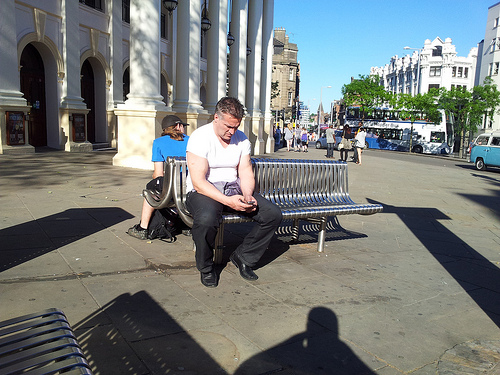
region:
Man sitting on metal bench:
[185, 95, 282, 286]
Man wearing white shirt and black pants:
[183, 98, 277, 286]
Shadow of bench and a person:
[10, 287, 392, 373]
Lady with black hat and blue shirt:
[128, 112, 188, 244]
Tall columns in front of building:
[114, 0, 274, 147]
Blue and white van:
[467, 124, 499, 173]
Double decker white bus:
[342, 97, 454, 157]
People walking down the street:
[280, 116, 367, 162]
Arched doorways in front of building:
[13, 27, 118, 156]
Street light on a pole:
[401, 45, 425, 94]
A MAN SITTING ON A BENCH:
[174, 94, 392, 291]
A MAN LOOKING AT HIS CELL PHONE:
[185, 95, 287, 290]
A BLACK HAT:
[156, 112, 194, 130]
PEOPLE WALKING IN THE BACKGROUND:
[336, 120, 368, 166]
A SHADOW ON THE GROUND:
[226, 303, 383, 372]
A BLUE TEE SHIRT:
[149, 132, 195, 165]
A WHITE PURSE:
[335, 139, 345, 151]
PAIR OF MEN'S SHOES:
[195, 249, 269, 290]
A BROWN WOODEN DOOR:
[17, 39, 52, 154]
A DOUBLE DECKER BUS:
[339, 99, 462, 159]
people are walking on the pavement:
[337, 118, 412, 199]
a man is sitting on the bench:
[183, 96, 384, 292]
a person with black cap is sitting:
[125, 114, 189, 243]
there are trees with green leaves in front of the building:
[342, 41, 495, 158]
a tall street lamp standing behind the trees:
[394, 43, 436, 156]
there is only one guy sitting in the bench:
[175, 95, 389, 288]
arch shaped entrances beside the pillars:
[15, 17, 290, 159]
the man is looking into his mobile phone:
[180, 95, 283, 290]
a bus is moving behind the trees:
[322, 73, 458, 156]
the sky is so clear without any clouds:
[281, 3, 496, 70]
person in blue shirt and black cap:
[129, 117, 194, 237]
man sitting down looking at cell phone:
[181, 98, 286, 285]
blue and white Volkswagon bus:
[467, 133, 499, 168]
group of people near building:
[274, 116, 364, 161]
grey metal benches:
[136, 156, 381, 253]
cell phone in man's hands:
[236, 195, 253, 210]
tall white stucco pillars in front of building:
[121, 0, 275, 167]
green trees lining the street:
[349, 74, 498, 150]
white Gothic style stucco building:
[367, 39, 476, 148]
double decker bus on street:
[338, 101, 455, 154]